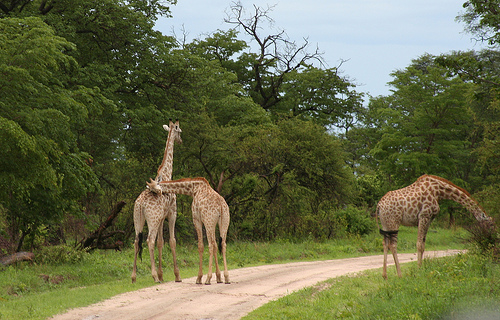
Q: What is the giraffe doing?
A: Playing.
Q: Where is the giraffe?
A: In the grass.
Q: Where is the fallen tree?
A: In the grass.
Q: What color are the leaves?
A: Green.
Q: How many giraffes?
A: Three.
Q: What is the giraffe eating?
A: A bush.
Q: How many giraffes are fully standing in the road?
A: One.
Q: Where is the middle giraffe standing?
A: Dirt road.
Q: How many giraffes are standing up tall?
A: One.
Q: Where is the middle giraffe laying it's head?
A: On giraffe's back.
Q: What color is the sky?
A: Blue.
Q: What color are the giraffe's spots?
A: Brown.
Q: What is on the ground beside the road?
A: Grass.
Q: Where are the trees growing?
A: On the side of the road.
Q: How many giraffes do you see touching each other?
A: Two.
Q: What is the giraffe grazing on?
A: Vegetation.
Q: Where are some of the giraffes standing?
A: On a sandy dirt road.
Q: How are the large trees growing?
A: In lines of the dirt road.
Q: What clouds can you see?
A: None.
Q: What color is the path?
A: Brownish pink.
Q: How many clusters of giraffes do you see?
A: One.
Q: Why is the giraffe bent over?
A: Eating.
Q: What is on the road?
A: Giraffe.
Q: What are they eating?
A: Leaves.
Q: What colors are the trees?
A: Green.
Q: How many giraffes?
A: 3.